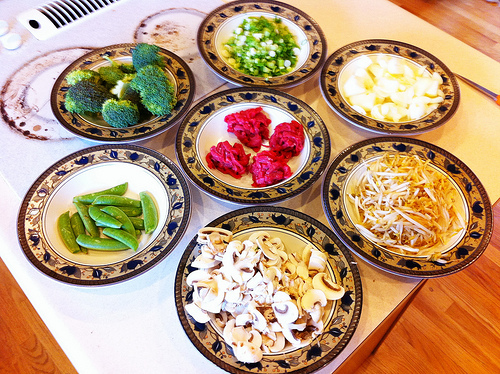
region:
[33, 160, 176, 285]
plate of food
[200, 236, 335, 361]
plate of food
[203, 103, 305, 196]
plate of food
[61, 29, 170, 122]
plate of food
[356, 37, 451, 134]
plate of food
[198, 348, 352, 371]
floral pattern on the rim of plate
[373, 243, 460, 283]
floral pattern on the rim of plate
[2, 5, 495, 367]
several dishes on the table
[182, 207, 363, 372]
a pile of mushrooms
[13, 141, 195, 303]
greens in the bowl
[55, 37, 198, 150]
a pile of broccoli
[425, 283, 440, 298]
spot on the wood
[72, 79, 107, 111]
head of the broccoli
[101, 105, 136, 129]
top of the broccoli is dark green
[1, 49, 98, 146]
an empty plate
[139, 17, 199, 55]
stains on the plate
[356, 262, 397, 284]
shadow from the bowl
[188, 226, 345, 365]
sliced mushrooms on a plate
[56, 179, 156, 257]
sugar snap peas on a plate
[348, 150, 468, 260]
bean sprouts on a plate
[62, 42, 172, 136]
broccoli chunks on a plate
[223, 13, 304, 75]
chopped green onion on a plate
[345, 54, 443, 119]
cauliflower chunks on a plate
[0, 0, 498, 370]
a light brown wood table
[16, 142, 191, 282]
a blue patterned china plate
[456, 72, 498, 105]
a sharp knife next to a plate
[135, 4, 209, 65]
a stain next to plates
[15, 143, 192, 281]
a black brown and white plate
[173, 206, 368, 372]
a black brown and white plate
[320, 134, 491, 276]
a black brown and white plate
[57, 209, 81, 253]
a long green string bean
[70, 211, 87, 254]
a long green string bean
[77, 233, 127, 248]
a long green string bean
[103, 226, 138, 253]
a long green string bean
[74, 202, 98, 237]
a long green string bean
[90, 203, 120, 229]
a long green string bean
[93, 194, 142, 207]
a long green string bean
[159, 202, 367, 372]
plate on a table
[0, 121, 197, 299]
plate on a table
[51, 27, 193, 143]
plate on a table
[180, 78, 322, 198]
plate on a table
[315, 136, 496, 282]
plate on a table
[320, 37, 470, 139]
plate on a table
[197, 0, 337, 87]
plate on a table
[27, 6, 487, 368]
bunch of plate on a table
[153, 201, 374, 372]
food plate on a table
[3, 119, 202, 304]
food plate on a table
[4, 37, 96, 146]
a plate made for dining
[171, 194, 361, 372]
a plate made for dining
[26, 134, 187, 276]
a plate made for dining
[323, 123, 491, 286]
a plate made for dining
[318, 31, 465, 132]
a plate made for dining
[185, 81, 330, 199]
a plate made for dining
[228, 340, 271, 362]
mushroom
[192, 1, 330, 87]
a plate made for dining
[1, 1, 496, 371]
a normal table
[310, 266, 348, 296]
mushroom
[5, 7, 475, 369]
several bowls of food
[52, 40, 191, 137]
a bowl of broccoli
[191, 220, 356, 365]
a bowl of mushrooms